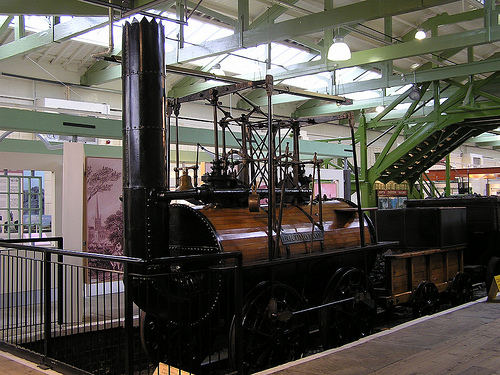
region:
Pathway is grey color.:
[389, 331, 496, 373]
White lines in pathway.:
[311, 315, 442, 372]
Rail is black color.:
[22, 225, 132, 355]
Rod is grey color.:
[176, 3, 419, 87]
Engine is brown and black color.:
[105, 100, 440, 291]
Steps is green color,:
[383, 100, 466, 151]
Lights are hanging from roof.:
[286, 16, 443, 106]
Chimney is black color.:
[99, 40, 177, 300]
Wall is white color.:
[53, 150, 85, 233]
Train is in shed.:
[67, 203, 322, 368]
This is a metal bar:
[79, 264, 93, 374]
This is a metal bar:
[49, 259, 59, 363]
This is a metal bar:
[0, 241, 149, 277]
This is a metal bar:
[10, 229, 76, 247]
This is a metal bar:
[0, 13, 112, 55]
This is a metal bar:
[259, 73, 275, 249]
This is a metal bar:
[172, 56, 369, 113]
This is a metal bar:
[297, 52, 480, 86]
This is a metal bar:
[317, 89, 452, 134]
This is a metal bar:
[354, 110, 388, 218]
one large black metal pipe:
[118, 15, 170, 302]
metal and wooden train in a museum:
[29, 22, 497, 367]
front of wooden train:
[156, 195, 381, 373]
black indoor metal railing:
[2, 240, 134, 374]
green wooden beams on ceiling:
[12, 5, 491, 145]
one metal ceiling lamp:
[326, 22, 351, 65]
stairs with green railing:
[356, 77, 498, 194]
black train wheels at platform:
[224, 275, 499, 374]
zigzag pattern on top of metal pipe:
[118, 13, 165, 39]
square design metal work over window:
[3, 165, 55, 245]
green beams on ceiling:
[0, 4, 495, 123]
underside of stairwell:
[360, 92, 485, 184]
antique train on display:
[119, 19, 464, 356]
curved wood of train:
[201, 198, 376, 272]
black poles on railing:
[0, 235, 147, 373]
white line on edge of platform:
[272, 293, 497, 373]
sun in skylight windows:
[120, 4, 382, 100]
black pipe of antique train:
[121, 19, 220, 320]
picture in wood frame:
[82, 155, 127, 285]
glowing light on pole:
[327, 21, 352, 63]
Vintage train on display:
[6, 25, 481, 365]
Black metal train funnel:
[111, 19, 170, 260]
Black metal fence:
[1, 237, 176, 373]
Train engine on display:
[114, 142, 375, 347]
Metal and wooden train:
[168, 193, 385, 284]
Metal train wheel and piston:
[219, 265, 394, 361]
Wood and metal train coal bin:
[377, 242, 479, 312]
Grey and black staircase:
[353, 107, 472, 194]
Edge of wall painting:
[77, 147, 157, 290]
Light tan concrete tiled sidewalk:
[381, 295, 497, 372]